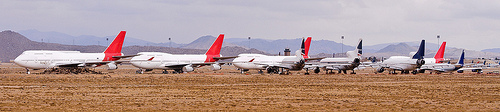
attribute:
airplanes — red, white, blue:
[16, 27, 470, 74]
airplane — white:
[18, 29, 123, 70]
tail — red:
[103, 31, 123, 65]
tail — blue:
[409, 40, 427, 60]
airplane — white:
[376, 38, 423, 70]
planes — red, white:
[14, 25, 223, 74]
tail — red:
[107, 27, 125, 57]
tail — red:
[203, 34, 223, 61]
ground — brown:
[2, 71, 498, 105]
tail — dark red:
[205, 33, 223, 60]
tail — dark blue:
[414, 40, 426, 69]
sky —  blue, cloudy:
[2, 0, 498, 52]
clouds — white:
[311, 6, 409, 30]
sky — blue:
[3, 2, 484, 45]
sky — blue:
[5, 4, 485, 50]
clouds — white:
[269, 7, 452, 40]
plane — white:
[13, 30, 137, 76]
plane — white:
[129, 32, 241, 76]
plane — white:
[228, 34, 321, 71]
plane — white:
[304, 39, 367, 79]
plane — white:
[368, 39, 430, 73]